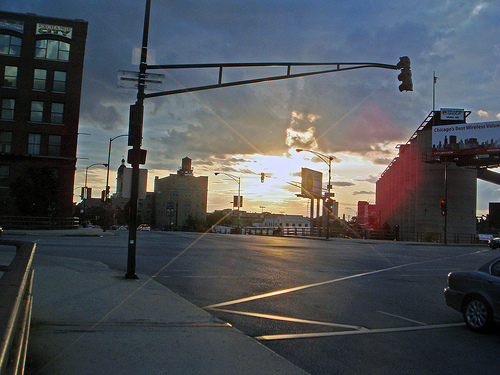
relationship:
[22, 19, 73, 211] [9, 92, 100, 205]
buildng has front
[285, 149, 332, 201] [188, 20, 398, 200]
billboard against sky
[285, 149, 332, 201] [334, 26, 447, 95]
billboard near light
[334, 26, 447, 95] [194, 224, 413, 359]
light over street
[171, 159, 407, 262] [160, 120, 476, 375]
lightposts in background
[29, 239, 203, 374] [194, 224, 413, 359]
sidewalk by road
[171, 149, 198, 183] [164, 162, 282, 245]
tower on building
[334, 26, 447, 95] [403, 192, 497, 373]
light for traffic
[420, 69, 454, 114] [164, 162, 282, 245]
pole on building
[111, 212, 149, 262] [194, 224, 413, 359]
button for crosswalk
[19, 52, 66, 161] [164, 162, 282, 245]
windows on building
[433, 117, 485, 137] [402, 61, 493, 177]
text on sign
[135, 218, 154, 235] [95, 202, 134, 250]
lights on cars